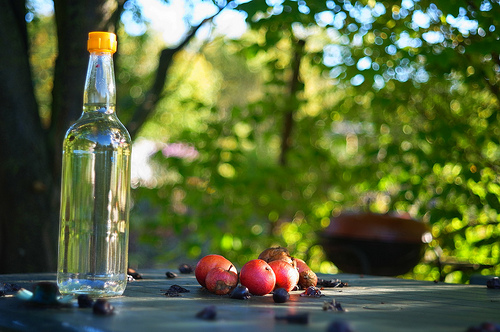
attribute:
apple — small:
[207, 263, 237, 294]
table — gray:
[1, 267, 500, 328]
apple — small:
[242, 259, 278, 293]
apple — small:
[195, 254, 237, 284]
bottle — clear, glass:
[57, 33, 134, 298]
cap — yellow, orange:
[85, 30, 118, 53]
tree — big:
[2, 3, 500, 283]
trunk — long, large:
[1, 130, 76, 273]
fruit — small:
[195, 247, 319, 295]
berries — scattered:
[4, 261, 500, 330]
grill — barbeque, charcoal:
[312, 193, 434, 275]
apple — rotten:
[261, 245, 295, 265]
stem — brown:
[227, 262, 235, 272]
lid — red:
[316, 189, 439, 244]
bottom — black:
[315, 231, 427, 275]